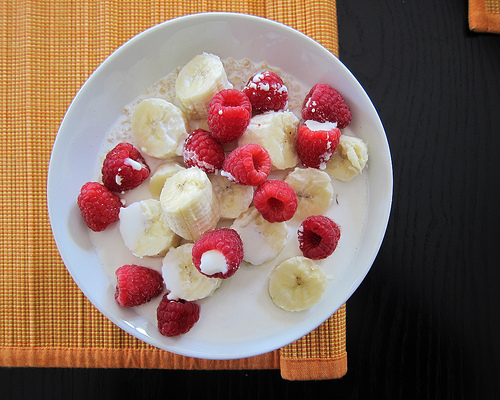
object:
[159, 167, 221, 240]
bananas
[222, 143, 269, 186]
berry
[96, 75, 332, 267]
milk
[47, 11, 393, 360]
bowl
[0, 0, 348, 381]
table